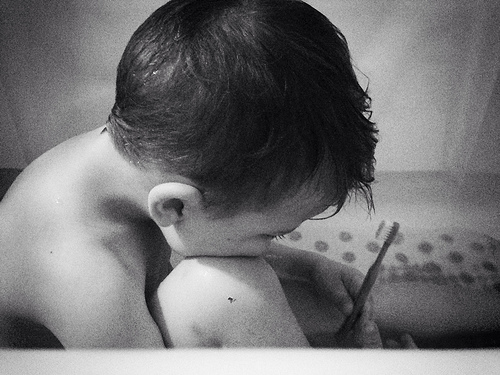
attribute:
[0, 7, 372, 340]
child —  resting, holding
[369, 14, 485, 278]
curtain — Shower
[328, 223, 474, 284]
dots — polka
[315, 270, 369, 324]
hand — Small, holding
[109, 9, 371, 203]
hair — brown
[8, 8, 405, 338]
boy — Naked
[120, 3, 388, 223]
hair — wet